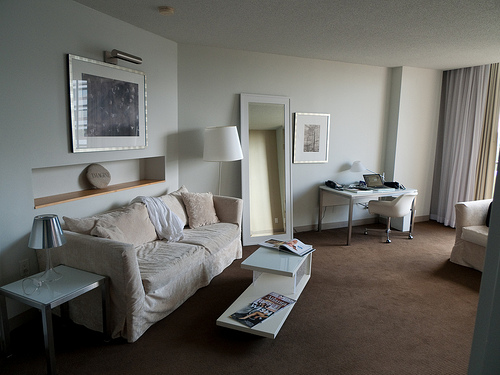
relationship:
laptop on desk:
[362, 170, 389, 190] [313, 184, 419, 245]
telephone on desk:
[323, 177, 344, 194] [313, 177, 420, 245]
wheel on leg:
[385, 237, 392, 244] [386, 216, 391, 242]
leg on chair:
[386, 216, 391, 242] [362, 189, 418, 244]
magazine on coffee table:
[226, 288, 297, 328] [215, 239, 315, 341]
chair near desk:
[360, 188, 422, 245] [309, 171, 421, 251]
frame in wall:
[289, 110, 331, 164] [271, 77, 356, 206]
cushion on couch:
[63, 202, 158, 243] [40, 185, 247, 342]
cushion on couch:
[462, 224, 488, 249] [447, 196, 493, 273]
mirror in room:
[234, 90, 295, 245] [15, 13, 487, 357]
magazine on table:
[226, 288, 297, 328] [232, 244, 301, 321]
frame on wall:
[289, 110, 331, 164] [178, 54, 408, 227]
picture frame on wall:
[53, 44, 163, 164] [9, 11, 167, 215]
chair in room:
[360, 188, 422, 245] [15, 13, 487, 357]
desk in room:
[313, 184, 419, 245] [1, 0, 498, 374]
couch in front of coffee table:
[40, 185, 247, 342] [214, 230, 316, 346]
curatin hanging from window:
[436, 61, 484, 231] [411, 50, 491, 245]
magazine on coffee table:
[254, 237, 317, 256] [215, 239, 315, 341]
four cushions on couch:
[54, 186, 223, 241] [40, 185, 247, 342]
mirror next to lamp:
[234, 90, 295, 245] [198, 124, 238, 187]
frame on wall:
[289, 110, 331, 164] [290, 109, 332, 166]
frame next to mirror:
[289, 110, 331, 164] [234, 90, 295, 245]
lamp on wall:
[98, 35, 156, 70] [1, 0, 180, 338]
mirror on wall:
[234, 90, 295, 245] [170, 34, 452, 244]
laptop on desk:
[362, 170, 389, 190] [313, 177, 420, 245]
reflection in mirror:
[254, 123, 280, 228] [250, 105, 285, 229]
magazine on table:
[226, 288, 297, 328] [241, 265, 304, 335]